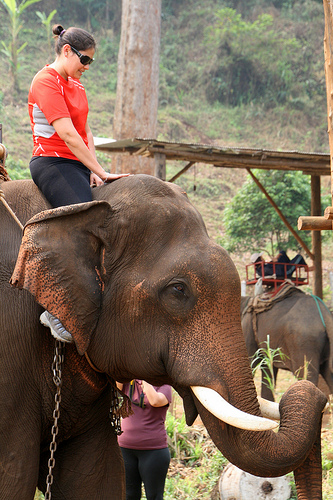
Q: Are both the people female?
A: Yes, all the people are female.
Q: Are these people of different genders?
A: No, all the people are female.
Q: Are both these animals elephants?
A: Yes, all the animals are elephants.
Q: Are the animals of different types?
A: No, all the animals are elephants.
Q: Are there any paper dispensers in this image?
A: No, there are no paper dispensers.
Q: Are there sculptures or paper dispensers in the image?
A: No, there are no paper dispensers or sculptures.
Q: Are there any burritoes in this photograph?
A: No, there are no burritoes.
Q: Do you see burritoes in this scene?
A: No, there are no burritoes.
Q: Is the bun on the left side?
A: Yes, the bun is on the left of the image.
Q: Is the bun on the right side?
A: No, the bun is on the left of the image.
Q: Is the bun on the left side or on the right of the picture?
A: The bun is on the left of the image.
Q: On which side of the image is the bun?
A: The bun is on the left of the image.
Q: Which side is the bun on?
A: The bun is on the left of the image.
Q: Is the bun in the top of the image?
A: Yes, the bun is in the top of the image.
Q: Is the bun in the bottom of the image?
A: No, the bun is in the top of the image.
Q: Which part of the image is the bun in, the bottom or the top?
A: The bun is in the top of the image.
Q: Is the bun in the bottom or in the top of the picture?
A: The bun is in the top of the image.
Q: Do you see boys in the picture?
A: No, there are no boys.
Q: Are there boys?
A: No, there are no boys.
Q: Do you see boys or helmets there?
A: No, there are no boys or helmets.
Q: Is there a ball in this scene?
A: No, there are no balls.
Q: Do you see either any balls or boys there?
A: No, there are no balls or boys.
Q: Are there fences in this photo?
A: No, there are no fences.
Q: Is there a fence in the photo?
A: No, there are no fences.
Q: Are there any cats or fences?
A: No, there are no fences or cats.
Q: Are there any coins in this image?
A: No, there are no coins.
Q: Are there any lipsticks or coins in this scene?
A: No, there are no coins or lipsticks.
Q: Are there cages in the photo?
A: No, there are no cages.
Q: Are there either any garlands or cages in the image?
A: No, there are no cages or garlands.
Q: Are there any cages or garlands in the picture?
A: No, there are no cages or garlands.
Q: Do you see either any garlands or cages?
A: No, there are no cages or garlands.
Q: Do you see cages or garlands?
A: No, there are no cages or garlands.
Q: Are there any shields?
A: No, there are no shields.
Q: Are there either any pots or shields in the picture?
A: No, there are no shields or pots.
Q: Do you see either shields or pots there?
A: No, there are no shields or pots.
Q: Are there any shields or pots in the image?
A: No, there are no shields or pots.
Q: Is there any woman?
A: Yes, there is a woman.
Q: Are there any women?
A: Yes, there is a woman.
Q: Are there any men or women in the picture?
A: Yes, there is a woman.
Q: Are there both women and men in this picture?
A: No, there is a woman but no men.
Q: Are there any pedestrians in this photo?
A: No, there are no pedestrians.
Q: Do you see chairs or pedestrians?
A: No, there are no pedestrians or chairs.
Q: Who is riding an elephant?
A: The woman is riding an elephant.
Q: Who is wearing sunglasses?
A: The woman is wearing sunglasses.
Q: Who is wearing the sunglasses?
A: The woman is wearing sunglasses.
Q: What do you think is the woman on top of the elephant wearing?
A: The woman is wearing sunglasses.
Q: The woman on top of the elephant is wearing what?
A: The woman is wearing sunglasses.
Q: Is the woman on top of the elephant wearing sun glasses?
A: Yes, the woman is wearing sun glasses.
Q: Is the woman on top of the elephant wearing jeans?
A: No, the woman is wearing sun glasses.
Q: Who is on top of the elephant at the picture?
A: The woman is on top of the elephant.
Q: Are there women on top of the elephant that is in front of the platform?
A: Yes, there is a woman on top of the elephant.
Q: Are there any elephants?
A: Yes, there is an elephant.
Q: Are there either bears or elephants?
A: Yes, there is an elephant.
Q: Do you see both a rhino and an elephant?
A: No, there is an elephant but no rhinos.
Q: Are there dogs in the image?
A: No, there are no dogs.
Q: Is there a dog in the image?
A: No, there are no dogs.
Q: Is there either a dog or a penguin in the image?
A: No, there are no dogs or penguins.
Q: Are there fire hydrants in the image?
A: No, there are no fire hydrants.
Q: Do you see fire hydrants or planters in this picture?
A: No, there are no fire hydrants or planters.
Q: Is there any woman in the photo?
A: Yes, there is a woman.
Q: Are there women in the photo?
A: Yes, there is a woman.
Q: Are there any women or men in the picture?
A: Yes, there is a woman.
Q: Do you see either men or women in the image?
A: Yes, there is a woman.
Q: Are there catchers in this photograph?
A: No, there are no catchers.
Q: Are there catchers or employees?
A: No, there are no catchers or employees.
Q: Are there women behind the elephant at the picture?
A: Yes, there is a woman behind the elephant.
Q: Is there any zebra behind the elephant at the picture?
A: No, there is a woman behind the elephant.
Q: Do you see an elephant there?
A: Yes, there is an elephant.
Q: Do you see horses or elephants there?
A: Yes, there is an elephant.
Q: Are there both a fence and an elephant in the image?
A: No, there is an elephant but no fences.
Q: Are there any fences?
A: No, there are no fences.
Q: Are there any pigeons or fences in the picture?
A: No, there are no fences or pigeons.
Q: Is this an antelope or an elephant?
A: This is an elephant.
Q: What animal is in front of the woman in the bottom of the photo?
A: The elephant is in front of the woman.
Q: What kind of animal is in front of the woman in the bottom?
A: The animal is an elephant.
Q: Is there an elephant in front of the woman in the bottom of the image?
A: Yes, there is an elephant in front of the woman.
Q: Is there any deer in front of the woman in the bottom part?
A: No, there is an elephant in front of the woman.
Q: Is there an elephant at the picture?
A: Yes, there is an elephant at the picture.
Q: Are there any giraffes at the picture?
A: No, there is an elephant at the picture.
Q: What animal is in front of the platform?
A: The elephant is in front of the platform.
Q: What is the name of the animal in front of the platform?
A: The animal is an elephant.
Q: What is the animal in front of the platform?
A: The animal is an elephant.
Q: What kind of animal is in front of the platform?
A: The animal is an elephant.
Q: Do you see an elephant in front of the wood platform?
A: Yes, there is an elephant in front of the platform.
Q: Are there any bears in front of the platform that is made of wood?
A: No, there is an elephant in front of the platform.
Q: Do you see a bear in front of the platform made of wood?
A: No, there is an elephant in front of the platform.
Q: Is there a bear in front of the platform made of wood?
A: No, there is an elephant in front of the platform.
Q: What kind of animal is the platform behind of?
A: The platform is behind the elephant.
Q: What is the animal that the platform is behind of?
A: The animal is an elephant.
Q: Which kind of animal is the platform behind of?
A: The platform is behind the elephant.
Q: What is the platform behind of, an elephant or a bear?
A: The platform is behind an elephant.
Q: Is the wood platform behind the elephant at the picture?
A: Yes, the platform is behind the elephant.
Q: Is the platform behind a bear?
A: No, the platform is behind the elephant.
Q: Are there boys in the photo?
A: No, there are no boys.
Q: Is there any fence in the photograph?
A: No, there are no fences.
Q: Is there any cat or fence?
A: No, there are no fences or cats.